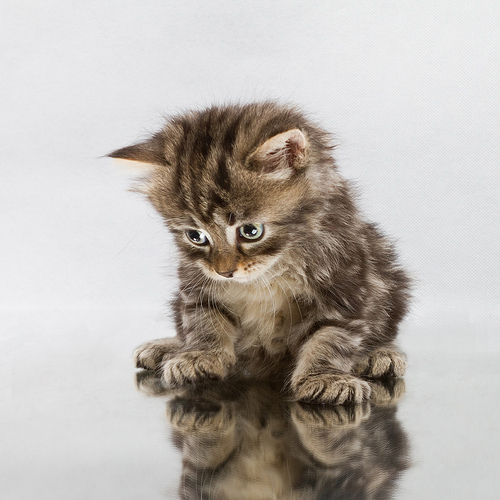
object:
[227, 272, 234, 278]
nostril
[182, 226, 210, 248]
eyes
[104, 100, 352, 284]
head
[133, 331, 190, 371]
leg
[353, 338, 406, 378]
leg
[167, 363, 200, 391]
paws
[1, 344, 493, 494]
table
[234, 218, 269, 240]
eyes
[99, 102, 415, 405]
cat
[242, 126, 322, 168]
ear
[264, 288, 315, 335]
whiskers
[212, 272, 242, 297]
mustache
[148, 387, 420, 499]
reflection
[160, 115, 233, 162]
fur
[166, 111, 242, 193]
stripes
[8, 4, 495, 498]
picture